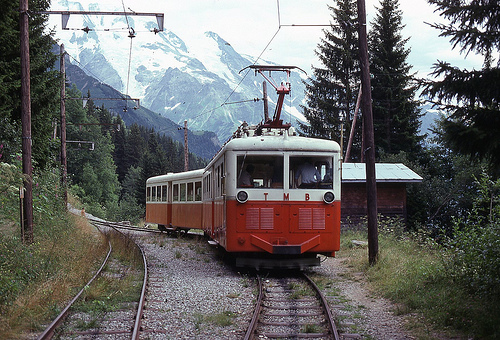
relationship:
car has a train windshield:
[146, 126, 343, 272] [237, 154, 333, 189]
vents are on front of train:
[241, 207, 330, 233] [199, 138, 339, 263]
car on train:
[142, 172, 172, 225] [145, 174, 173, 224]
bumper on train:
[251, 229, 325, 255] [199, 138, 339, 263]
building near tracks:
[315, 162, 423, 232] [250, 280, 323, 335]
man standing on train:
[294, 163, 321, 189] [225, 140, 345, 266]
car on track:
[146, 126, 343, 272] [250, 288, 334, 335]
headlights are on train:
[235, 190, 336, 204] [199, 138, 339, 263]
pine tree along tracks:
[325, 3, 407, 107] [255, 289, 342, 336]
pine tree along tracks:
[430, 6, 483, 117] [254, 283, 341, 327]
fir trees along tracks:
[3, 3, 213, 240] [30, 202, 150, 337]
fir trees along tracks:
[3, 3, 213, 240] [7, 0, 51, 163]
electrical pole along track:
[2, 15, 51, 251] [28, 185, 199, 332]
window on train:
[138, 181, 171, 204] [99, 84, 365, 281]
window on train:
[136, 179, 172, 205] [130, 132, 340, 271]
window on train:
[148, 181, 171, 207] [94, 93, 375, 311]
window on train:
[166, 174, 196, 207] [65, 112, 375, 296]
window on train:
[183, 180, 203, 207] [109, 90, 374, 290]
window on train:
[232, 149, 291, 189] [76, 110, 395, 278]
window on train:
[289, 155, 332, 189] [87, 120, 380, 299]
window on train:
[200, 167, 223, 208] [55, 90, 376, 304]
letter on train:
[255, 186, 274, 205] [190, 95, 373, 287]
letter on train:
[282, 183, 329, 211] [117, 100, 385, 303]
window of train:
[237, 155, 284, 189] [108, 111, 428, 298]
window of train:
[291, 148, 340, 190] [153, 125, 387, 268]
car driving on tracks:
[146, 126, 343, 272] [248, 271, 323, 328]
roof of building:
[314, 162, 422, 182] [335, 135, 445, 215]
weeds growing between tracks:
[69, 224, 140, 336] [41, 222, 147, 339]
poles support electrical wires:
[17, 0, 384, 270] [69, 0, 337, 139]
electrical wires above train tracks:
[69, 0, 337, 139] [39, 212, 341, 339]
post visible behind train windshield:
[357, 0, 378, 264] [239, 152, 333, 190]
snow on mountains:
[48, 3, 310, 123] [49, 0, 448, 168]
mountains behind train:
[49, 0, 448, 168] [139, 118, 341, 272]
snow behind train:
[48, 3, 310, 123] [139, 118, 341, 272]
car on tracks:
[146, 126, 343, 272] [88, 219, 340, 339]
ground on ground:
[1, 212, 498, 338] [1, 212, 498, 338]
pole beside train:
[353, 0, 380, 266] [139, 118, 341, 272]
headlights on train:
[322, 190, 336, 204] [139, 118, 341, 272]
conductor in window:
[293, 158, 322, 188] [287, 158, 333, 188]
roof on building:
[314, 162, 422, 182] [338, 162, 425, 226]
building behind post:
[342, 162, 423, 232] [357, 2, 379, 263]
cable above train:
[188, 2, 356, 129] [139, 118, 341, 272]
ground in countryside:
[1, 212, 498, 338] [6, 19, 494, 338]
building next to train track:
[342, 162, 423, 232] [32, 213, 357, 338]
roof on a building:
[340, 162, 422, 182] [342, 162, 423, 232]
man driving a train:
[292, 159, 322, 189] [139, 118, 341, 272]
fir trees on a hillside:
[3, 3, 213, 240] [0, 38, 222, 231]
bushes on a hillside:
[374, 173, 497, 336] [11, 181, 499, 338]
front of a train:
[225, 135, 341, 255] [139, 118, 341, 272]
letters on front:
[261, 190, 311, 202] [225, 135, 341, 255]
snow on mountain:
[48, 3, 310, 123] [20, 2, 470, 189]